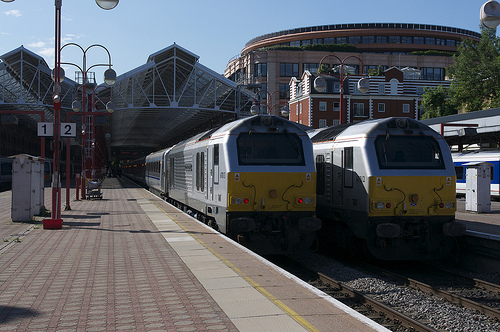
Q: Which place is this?
A: It is a walkway.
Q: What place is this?
A: It is a walkway.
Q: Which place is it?
A: It is a walkway.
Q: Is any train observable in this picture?
A: Yes, there is a train.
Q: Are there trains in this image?
A: Yes, there is a train.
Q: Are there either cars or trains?
A: Yes, there is a train.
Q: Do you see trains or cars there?
A: Yes, there is a train.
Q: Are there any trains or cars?
A: Yes, there is a train.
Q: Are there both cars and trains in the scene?
A: No, there is a train but no cars.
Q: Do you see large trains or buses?
A: Yes, there is a large train.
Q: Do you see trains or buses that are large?
A: Yes, the train is large.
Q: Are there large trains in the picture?
A: Yes, there is a large train.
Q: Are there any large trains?
A: Yes, there is a large train.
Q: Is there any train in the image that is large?
A: Yes, there is a train that is large.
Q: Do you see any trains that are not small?
A: Yes, there is a large train.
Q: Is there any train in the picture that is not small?
A: Yes, there is a large train.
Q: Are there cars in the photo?
A: No, there are no cars.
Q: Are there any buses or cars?
A: No, there are no cars or buses.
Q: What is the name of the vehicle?
A: The vehicle is a train.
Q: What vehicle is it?
A: The vehicle is a train.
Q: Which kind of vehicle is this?
A: This is a train.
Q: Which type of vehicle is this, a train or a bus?
A: This is a train.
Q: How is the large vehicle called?
A: The vehicle is a train.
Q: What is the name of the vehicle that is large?
A: The vehicle is a train.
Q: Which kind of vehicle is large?
A: The vehicle is a train.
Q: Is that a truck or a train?
A: That is a train.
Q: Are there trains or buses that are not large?
A: No, there is a train but it is large.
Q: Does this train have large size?
A: Yes, the train is large.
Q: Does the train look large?
A: Yes, the train is large.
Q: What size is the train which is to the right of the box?
A: The train is large.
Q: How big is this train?
A: The train is large.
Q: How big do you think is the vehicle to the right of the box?
A: The train is large.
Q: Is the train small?
A: No, the train is large.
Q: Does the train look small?
A: No, the train is large.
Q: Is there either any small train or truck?
A: No, there is a train but it is large.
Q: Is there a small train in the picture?
A: No, there is a train but it is large.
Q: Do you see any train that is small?
A: No, there is a train but it is large.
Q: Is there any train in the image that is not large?
A: No, there is a train but it is large.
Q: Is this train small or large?
A: The train is large.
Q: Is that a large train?
A: Yes, that is a large train.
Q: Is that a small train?
A: No, that is a large train.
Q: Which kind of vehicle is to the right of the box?
A: The vehicle is a train.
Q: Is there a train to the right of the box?
A: Yes, there is a train to the right of the box.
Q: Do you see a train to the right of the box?
A: Yes, there is a train to the right of the box.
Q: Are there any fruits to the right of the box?
A: No, there is a train to the right of the box.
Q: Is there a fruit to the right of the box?
A: No, there is a train to the right of the box.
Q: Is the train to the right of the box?
A: Yes, the train is to the right of the box.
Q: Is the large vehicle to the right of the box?
A: Yes, the train is to the right of the box.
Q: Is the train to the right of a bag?
A: No, the train is to the right of the box.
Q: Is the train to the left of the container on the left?
A: No, the train is to the right of the box.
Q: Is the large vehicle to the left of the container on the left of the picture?
A: No, the train is to the right of the box.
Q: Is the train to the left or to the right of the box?
A: The train is to the right of the box.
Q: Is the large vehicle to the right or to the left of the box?
A: The train is to the right of the box.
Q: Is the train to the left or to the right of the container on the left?
A: The train is to the right of the box.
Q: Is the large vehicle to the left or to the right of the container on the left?
A: The train is to the right of the box.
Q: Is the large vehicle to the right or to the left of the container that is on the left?
A: The train is to the right of the box.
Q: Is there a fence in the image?
A: No, there are no fences.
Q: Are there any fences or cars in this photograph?
A: No, there are no fences or cars.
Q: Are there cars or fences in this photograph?
A: No, there are no fences or cars.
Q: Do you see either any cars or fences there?
A: No, there are no fences or cars.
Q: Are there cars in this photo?
A: No, there are no cars.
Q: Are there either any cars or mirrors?
A: No, there are no cars or mirrors.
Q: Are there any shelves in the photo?
A: No, there are no shelves.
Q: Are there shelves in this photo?
A: No, there are no shelves.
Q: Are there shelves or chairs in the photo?
A: No, there are no shelves or chairs.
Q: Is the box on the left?
A: Yes, the box is on the left of the image.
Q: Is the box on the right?
A: No, the box is on the left of the image.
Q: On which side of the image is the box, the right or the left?
A: The box is on the left of the image.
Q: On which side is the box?
A: The box is on the left of the image.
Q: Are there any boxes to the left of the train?
A: Yes, there is a box to the left of the train.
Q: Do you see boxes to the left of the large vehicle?
A: Yes, there is a box to the left of the train.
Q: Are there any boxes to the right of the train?
A: No, the box is to the left of the train.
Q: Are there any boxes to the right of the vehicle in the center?
A: No, the box is to the left of the train.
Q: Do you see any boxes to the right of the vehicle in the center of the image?
A: No, the box is to the left of the train.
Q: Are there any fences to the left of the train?
A: No, there is a box to the left of the train.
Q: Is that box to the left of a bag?
A: No, the box is to the left of a train.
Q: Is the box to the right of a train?
A: No, the box is to the left of a train.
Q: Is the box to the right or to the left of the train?
A: The box is to the left of the train.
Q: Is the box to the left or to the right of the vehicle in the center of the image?
A: The box is to the left of the train.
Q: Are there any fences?
A: No, there are no fences.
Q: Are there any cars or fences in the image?
A: No, there are no fences or cars.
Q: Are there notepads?
A: No, there are no notepads.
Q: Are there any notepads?
A: No, there are no notepads.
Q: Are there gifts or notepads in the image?
A: No, there are no notepads or gifts.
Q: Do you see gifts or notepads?
A: No, there are no notepads or gifts.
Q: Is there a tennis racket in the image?
A: No, there are no rackets.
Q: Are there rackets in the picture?
A: No, there are no rackets.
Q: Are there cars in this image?
A: No, there are no cars.